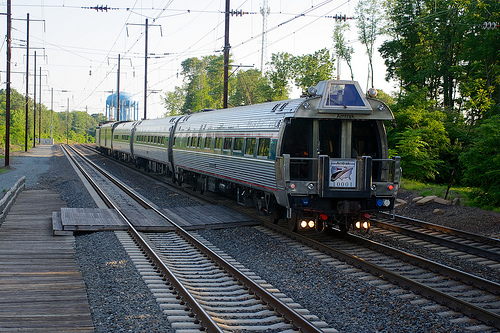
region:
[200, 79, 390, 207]
this is a train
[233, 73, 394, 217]
the train is moving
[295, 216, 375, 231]
the lights are on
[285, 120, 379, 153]
the door is open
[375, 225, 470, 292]
these are the rails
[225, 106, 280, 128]
the train is metallic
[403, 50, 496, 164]
these are the leaves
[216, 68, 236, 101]
this is a pole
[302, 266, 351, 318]
small stones are in the middle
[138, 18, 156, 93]
the pole is straight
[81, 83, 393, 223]
Train on train tracks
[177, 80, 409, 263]
Silver train on the tracks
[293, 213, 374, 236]
Head lights on a train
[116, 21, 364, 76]
Electric lines above a train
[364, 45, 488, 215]
trees near the train track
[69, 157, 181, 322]
Gravel near train tracks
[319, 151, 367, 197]
sign on a train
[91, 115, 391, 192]
Four train cars on the track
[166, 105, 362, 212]
Red and silver train car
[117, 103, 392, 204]
locomotive on the tracks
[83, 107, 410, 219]
train on the tracks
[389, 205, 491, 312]
tracks train is traveling on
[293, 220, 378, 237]
lights on the train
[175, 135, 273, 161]
window on side of train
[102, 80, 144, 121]
water tower in the distance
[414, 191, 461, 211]
rocks on the side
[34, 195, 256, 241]
board across the tracks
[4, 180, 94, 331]
board along side of tracks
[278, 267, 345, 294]
rocks and gravel between tracks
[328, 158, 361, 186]
image on car of train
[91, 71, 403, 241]
silver metal train moving down train tracks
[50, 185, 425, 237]
gray wooden walkway across train tracks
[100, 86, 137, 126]
circular light blue water tower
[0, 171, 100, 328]
brown and gray wooden walkway along train tracks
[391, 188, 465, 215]
light beige rocks next to train tracks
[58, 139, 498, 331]
metal train tracks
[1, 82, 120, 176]
row of green trees along train tracks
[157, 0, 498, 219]
row of green trees along train tracks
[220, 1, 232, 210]
thick wooden pole next to train tracks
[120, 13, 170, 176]
power line support pole next to train tracks